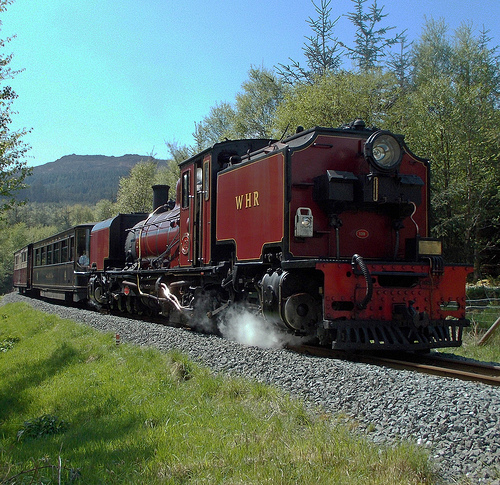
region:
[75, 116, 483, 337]
OLD RED TRAIN ON TRACKS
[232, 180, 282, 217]
YELLOW WHR ON SIDE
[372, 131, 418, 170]
ROUND HEADLIGHT ON TRAIN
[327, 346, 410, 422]
GRAY GRAVEL NEAR TRACKS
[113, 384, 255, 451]
GREEN GRASS ON GROUND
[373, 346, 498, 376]
METAL RAILS ON TRACKS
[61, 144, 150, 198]
MOUNTAINS IN DISTANCE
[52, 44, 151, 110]
BLUE SKY ABOVE MOUNTAINS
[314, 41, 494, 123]
THICK FOREST ON RIGHT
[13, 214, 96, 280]
PASSENGER CARS ON TRAIN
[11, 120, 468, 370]
train coming down the tracks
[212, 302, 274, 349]
smoke coming off the train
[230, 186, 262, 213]
gold lettering on red background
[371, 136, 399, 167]
light on the front of the train car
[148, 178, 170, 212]
smoke pipe on top of train car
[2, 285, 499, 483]
gravel around the train tracks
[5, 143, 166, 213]
mountain in the distance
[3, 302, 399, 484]
grass beside the gravel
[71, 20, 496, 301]
trees beside the train tracks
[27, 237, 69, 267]
windows on side of train car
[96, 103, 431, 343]
this is the train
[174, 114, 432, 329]
the train is in motion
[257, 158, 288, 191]
the train is red in color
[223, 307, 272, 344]
this is the smoke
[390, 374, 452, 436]
these are the small stones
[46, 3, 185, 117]
this is the sky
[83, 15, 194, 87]
the sky is clear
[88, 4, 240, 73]
the sky is blue in color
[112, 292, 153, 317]
these are the wheels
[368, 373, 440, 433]
the stones are several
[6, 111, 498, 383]
a locomotive on a railroad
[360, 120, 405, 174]
a headlight on top of locomotive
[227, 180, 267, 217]
yellow words on side of locomotive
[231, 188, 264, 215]
yellow words WHR on side locomotive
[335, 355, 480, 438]
the gravel is gray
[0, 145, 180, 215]
a mountain on the background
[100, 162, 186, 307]
the engine of locomotive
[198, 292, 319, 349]
smoke under locomotive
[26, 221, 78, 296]
the car has windows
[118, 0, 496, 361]
green trees behind a locomotive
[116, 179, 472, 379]
scene at a railway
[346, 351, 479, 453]
the place is rockky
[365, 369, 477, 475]
the rocks are grey in color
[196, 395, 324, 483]
the floor is green in color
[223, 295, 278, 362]
the moke is white in color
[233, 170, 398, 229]
the train is maroon in color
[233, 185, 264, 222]
the words are written ojn a maroon plate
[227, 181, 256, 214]
the wrds re written in yellow color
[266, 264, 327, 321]
the train is metallic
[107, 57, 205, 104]
the sky is clear and blue in colour